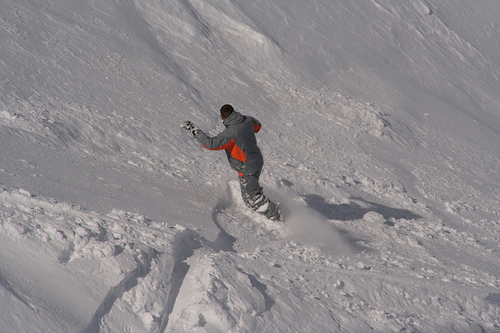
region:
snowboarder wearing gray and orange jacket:
[192, 89, 279, 219]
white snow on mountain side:
[22, 2, 106, 106]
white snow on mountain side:
[22, 85, 102, 187]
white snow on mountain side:
[2, 195, 84, 306]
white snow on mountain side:
[103, 187, 200, 308]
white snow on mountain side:
[179, 230, 307, 295]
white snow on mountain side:
[316, 232, 413, 309]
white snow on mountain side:
[401, 143, 469, 244]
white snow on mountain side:
[302, 96, 377, 180]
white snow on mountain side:
[111, 19, 252, 64]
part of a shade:
[333, 191, 367, 230]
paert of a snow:
[259, 262, 287, 312]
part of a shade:
[327, 180, 358, 222]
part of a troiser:
[244, 169, 271, 199]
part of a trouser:
[243, 168, 269, 206]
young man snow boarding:
[182, 95, 289, 225]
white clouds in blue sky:
[13, 13, 98, 103]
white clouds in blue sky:
[25, 99, 119, 184]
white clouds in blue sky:
[31, 176, 113, 271]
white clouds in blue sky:
[112, 196, 187, 277]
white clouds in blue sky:
[186, 226, 326, 294]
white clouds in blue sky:
[311, 180, 412, 277]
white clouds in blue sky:
[103, 32, 230, 94]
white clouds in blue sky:
[306, 25, 436, 95]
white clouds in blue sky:
[335, 75, 423, 153]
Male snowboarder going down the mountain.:
[182, 101, 280, 228]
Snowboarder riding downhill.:
[180, 98, 285, 233]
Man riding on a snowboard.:
[180, 97, 285, 234]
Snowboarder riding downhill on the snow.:
[179, 100, 286, 229]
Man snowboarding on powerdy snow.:
[178, 100, 282, 228]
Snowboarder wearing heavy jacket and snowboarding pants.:
[181, 100, 287, 222]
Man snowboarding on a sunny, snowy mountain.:
[180, 100, 285, 220]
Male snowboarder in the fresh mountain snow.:
[179, 100, 281, 222]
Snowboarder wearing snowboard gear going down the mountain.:
[181, 100, 286, 224]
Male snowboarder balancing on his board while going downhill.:
[183, 98, 280, 223]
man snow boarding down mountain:
[162, 91, 303, 241]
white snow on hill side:
[5, 10, 131, 99]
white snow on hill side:
[2, 66, 98, 136]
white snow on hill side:
[110, 84, 175, 167]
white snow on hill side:
[29, 136, 113, 201]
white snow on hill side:
[27, 219, 131, 297]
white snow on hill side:
[143, 210, 248, 286]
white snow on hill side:
[242, 244, 333, 296]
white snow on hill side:
[364, 162, 461, 290]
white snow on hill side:
[301, 50, 426, 140]